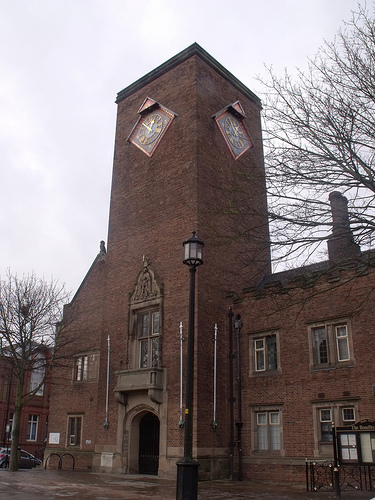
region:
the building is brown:
[60, 36, 374, 425]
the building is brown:
[52, 65, 355, 467]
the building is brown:
[56, 52, 369, 499]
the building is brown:
[57, 60, 321, 490]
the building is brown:
[55, 76, 342, 490]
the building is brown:
[75, 88, 336, 498]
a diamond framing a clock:
[125, 92, 179, 161]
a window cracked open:
[242, 327, 283, 379]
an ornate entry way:
[111, 253, 170, 486]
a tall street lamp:
[171, 229, 204, 499]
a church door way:
[114, 400, 161, 477]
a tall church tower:
[86, 39, 274, 490]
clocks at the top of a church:
[123, 92, 256, 163]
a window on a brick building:
[247, 400, 286, 456]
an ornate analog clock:
[136, 113, 164, 145]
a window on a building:
[253, 412, 269, 431]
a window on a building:
[268, 410, 282, 428]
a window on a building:
[334, 323, 351, 337]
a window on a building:
[309, 319, 332, 367]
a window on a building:
[318, 410, 335, 444]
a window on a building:
[341, 406, 350, 421]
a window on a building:
[152, 313, 164, 337]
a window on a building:
[27, 414, 44, 432]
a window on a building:
[68, 411, 84, 446]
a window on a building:
[75, 355, 102, 383]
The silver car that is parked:
[0, 440, 43, 474]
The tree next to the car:
[2, 265, 70, 471]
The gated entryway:
[113, 407, 183, 487]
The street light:
[167, 235, 219, 498]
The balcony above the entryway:
[103, 362, 173, 401]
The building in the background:
[5, 333, 47, 471]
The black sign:
[323, 413, 373, 478]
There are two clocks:
[110, 94, 264, 162]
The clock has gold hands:
[136, 115, 159, 131]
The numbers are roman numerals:
[132, 110, 165, 146]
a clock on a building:
[132, 76, 191, 163]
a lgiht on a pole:
[175, 233, 203, 284]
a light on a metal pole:
[170, 231, 204, 266]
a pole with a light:
[171, 218, 209, 274]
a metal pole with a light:
[164, 219, 222, 295]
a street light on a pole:
[167, 227, 211, 290]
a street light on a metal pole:
[164, 228, 212, 301]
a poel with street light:
[176, 231, 190, 291]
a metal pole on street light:
[166, 216, 215, 304]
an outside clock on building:
[119, 81, 188, 167]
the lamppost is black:
[161, 223, 209, 490]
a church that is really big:
[13, 59, 359, 475]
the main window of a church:
[110, 255, 175, 366]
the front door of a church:
[112, 387, 161, 475]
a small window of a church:
[58, 412, 94, 453]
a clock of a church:
[133, 101, 174, 152]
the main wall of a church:
[102, 164, 201, 252]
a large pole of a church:
[92, 331, 116, 444]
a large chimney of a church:
[313, 179, 363, 258]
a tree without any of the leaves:
[247, 84, 363, 189]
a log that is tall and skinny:
[4, 405, 32, 471]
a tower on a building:
[79, 34, 289, 330]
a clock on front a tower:
[125, 89, 180, 158]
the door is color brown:
[128, 406, 163, 480]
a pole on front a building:
[177, 319, 188, 431]